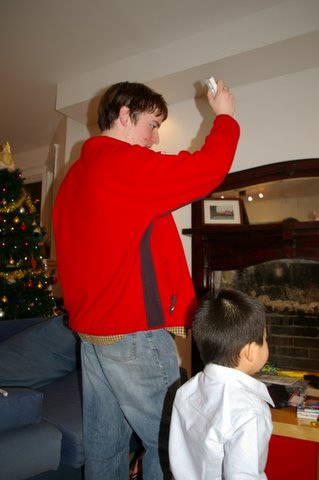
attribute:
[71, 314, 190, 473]
jeans — blue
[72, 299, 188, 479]
legs — man's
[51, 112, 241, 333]
jacket — red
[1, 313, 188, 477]
couch — blue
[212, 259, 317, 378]
fireplace — brick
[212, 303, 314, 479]
table — coffee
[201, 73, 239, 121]
wii remote — white 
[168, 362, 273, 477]
shirt — white 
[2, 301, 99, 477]
couch — blue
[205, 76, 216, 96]
controller — video game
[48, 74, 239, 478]
man — playing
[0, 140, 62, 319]
christmas tree — decorated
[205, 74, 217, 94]
game controller — wii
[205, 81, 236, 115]
hand — mans